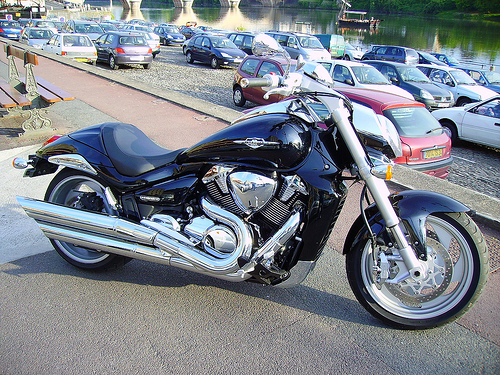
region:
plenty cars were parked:
[92, 7, 263, 119]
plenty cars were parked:
[122, 10, 309, 155]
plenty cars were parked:
[187, 37, 385, 127]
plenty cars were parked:
[197, 8, 298, 86]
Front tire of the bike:
[328, 192, 486, 328]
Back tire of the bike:
[31, 153, 142, 300]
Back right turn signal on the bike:
[4, 146, 31, 181]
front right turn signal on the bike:
[360, 151, 405, 214]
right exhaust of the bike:
[12, 162, 265, 317]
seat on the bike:
[90, 103, 198, 176]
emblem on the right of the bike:
[224, 131, 290, 157]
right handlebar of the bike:
[218, 63, 290, 98]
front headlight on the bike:
[366, 103, 421, 165]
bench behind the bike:
[0, 41, 107, 127]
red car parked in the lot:
[312, 67, 470, 193]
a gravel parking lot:
[125, 27, 248, 97]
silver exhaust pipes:
[15, 172, 257, 293]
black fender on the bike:
[323, 169, 473, 289]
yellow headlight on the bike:
[374, 153, 404, 187]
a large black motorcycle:
[15, 43, 496, 354]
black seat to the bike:
[93, 104, 213, 209]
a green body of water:
[385, 14, 492, 54]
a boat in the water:
[328, 0, 388, 58]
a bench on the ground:
[0, 36, 75, 128]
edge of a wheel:
[465, 282, 477, 315]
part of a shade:
[327, 308, 352, 318]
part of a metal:
[203, 261, 258, 294]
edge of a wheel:
[342, 280, 372, 317]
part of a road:
[253, 307, 299, 364]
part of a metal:
[28, 206, 90, 258]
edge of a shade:
[310, 302, 346, 337]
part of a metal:
[372, 196, 390, 232]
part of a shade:
[319, 300, 354, 321]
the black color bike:
[31, 83, 486, 331]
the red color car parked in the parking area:
[233, 48, 295, 96]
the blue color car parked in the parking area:
[182, 21, 240, 81]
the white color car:
[335, 55, 391, 90]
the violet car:
[101, 26, 157, 71]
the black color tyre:
[352, 177, 489, 337]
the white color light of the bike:
[372, 112, 409, 158]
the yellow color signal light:
[8, 155, 30, 175]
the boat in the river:
[330, 7, 387, 38]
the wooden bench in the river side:
[6, 41, 77, 118]